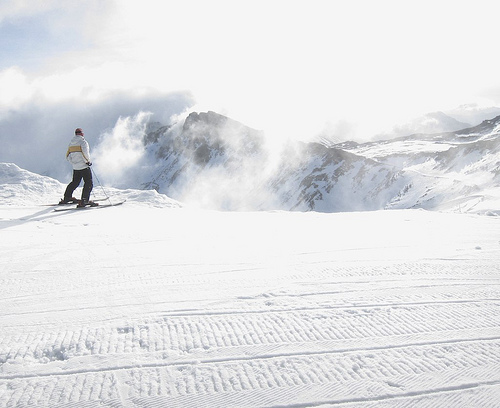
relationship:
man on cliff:
[51, 120, 107, 212] [133, 178, 253, 270]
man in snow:
[51, 120, 107, 212] [164, 226, 342, 323]